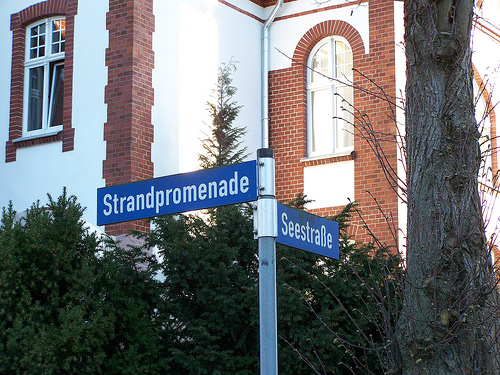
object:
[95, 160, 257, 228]
sign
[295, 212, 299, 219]
blue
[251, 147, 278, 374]
pole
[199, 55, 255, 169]
small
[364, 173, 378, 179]
bricks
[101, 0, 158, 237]
build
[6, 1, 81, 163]
build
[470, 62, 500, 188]
build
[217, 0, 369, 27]
build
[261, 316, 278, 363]
metal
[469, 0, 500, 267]
bare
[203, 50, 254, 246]
green tree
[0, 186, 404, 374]
green bushes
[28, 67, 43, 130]
window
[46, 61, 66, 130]
open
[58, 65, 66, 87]
frisbee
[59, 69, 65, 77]
white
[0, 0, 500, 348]
building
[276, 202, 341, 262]
street sign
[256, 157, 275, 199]
bolts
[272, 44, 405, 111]
branches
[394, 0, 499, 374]
trunk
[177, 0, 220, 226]
light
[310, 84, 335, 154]
windows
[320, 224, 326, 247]
letter